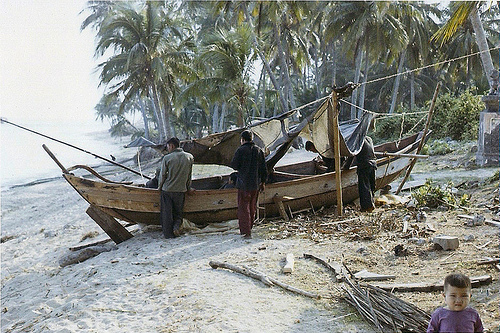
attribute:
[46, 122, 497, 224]
boat — sharp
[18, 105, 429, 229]
wooden boat — old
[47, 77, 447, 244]
boat — wood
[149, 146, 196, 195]
shirt — grey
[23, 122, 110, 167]
water — calm, light blue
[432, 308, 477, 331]
shirt — purple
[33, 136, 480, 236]
boat — wooden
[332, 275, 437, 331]
sticks — small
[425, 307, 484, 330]
shirt — purple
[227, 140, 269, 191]
jacket — black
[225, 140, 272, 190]
shirt — black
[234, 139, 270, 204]
shirt — black